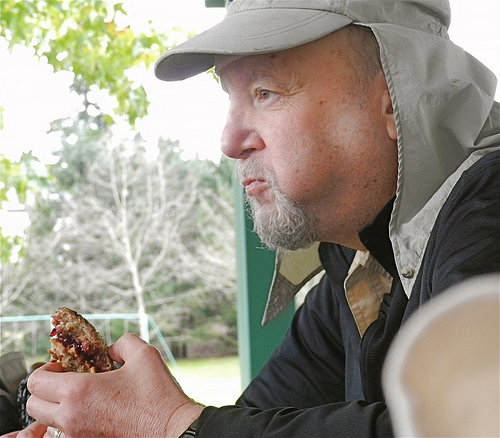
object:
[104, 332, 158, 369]
thumb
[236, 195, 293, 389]
pillar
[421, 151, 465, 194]
ground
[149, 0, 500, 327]
hat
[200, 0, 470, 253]
head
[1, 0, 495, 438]
man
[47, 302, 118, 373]
sandwich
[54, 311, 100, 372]
peanut butter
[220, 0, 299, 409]
window bar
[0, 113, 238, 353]
tree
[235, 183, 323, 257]
beard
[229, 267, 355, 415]
arm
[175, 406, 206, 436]
watch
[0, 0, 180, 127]
leaves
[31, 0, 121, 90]
leaves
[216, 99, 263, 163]
nose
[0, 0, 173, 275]
trees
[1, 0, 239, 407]
window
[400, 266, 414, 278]
button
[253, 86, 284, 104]
eye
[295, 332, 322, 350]
black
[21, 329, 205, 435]
hand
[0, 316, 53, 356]
fence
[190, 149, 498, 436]
jacket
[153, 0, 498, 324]
hood